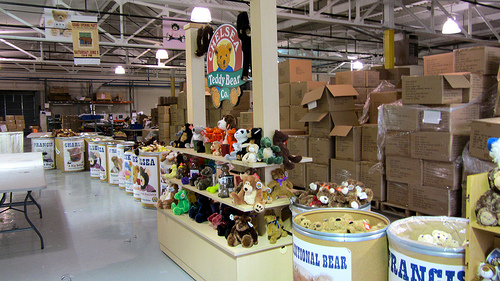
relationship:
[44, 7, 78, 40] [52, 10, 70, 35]
sign with teddy bear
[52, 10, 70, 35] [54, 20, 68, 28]
teddy bear with white shirt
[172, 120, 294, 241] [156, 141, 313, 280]
stuffed animals on display cabinet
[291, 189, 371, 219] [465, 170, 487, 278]
barrel between display cabinet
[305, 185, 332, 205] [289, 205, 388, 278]
stuffed animal in barrel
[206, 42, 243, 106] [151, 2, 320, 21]
teddy bear on ceiling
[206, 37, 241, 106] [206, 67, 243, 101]
teddy bear written written white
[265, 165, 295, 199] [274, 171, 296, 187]
stuffed animal has ribbon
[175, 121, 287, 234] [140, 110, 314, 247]
toys on shelf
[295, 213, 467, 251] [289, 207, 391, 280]
toys in barrel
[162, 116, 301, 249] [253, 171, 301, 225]
toys in shelves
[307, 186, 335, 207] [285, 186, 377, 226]
toy on barrel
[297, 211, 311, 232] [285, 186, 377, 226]
toy on barrel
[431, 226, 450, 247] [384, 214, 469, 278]
toy on barrel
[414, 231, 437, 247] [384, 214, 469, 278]
toy on barrel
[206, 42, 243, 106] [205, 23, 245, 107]
teddy bear on banner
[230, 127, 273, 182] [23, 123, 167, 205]
bears in bins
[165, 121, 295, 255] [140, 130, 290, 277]
stuffed animals in three shelves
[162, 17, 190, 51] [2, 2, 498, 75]
sign on ceiling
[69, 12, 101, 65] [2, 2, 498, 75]
sign on ceiling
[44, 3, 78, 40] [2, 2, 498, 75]
sign on ceiling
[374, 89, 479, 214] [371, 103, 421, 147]
boxes are wrapped in plastic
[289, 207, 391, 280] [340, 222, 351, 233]
barrel of traditional bear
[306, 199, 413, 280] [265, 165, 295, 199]
barrel of stuffed stuffed animal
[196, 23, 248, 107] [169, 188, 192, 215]
banner of a teddy bear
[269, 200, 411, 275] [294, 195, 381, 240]
barrel has toys